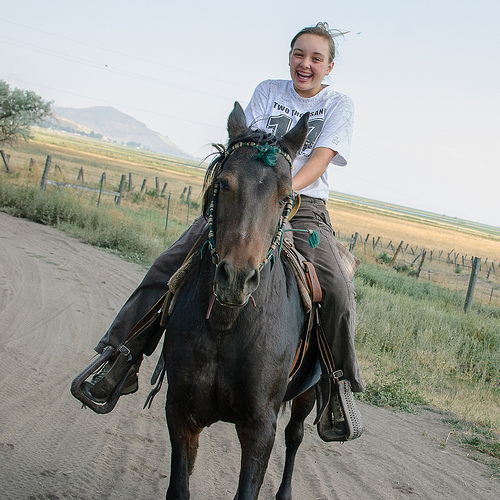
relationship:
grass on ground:
[0, 125, 497, 476] [2, 126, 499, 499]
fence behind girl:
[1, 148, 497, 317] [76, 22, 366, 435]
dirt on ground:
[0, 209, 499, 497] [2, 126, 499, 499]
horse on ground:
[142, 102, 356, 499] [2, 126, 499, 499]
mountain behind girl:
[20, 101, 204, 163] [76, 22, 366, 435]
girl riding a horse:
[76, 22, 366, 435] [142, 102, 356, 499]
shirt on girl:
[243, 81, 353, 204] [76, 22, 366, 435]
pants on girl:
[93, 194, 366, 393] [76, 22, 366, 435]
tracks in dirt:
[0, 210, 498, 498] [0, 209, 499, 497]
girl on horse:
[76, 22, 366, 435] [142, 102, 356, 499]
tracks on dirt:
[0, 210, 498, 498] [0, 209, 499, 497]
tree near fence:
[0, 80, 57, 147] [1, 148, 497, 317]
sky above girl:
[1, 1, 499, 228] [76, 22, 366, 435]